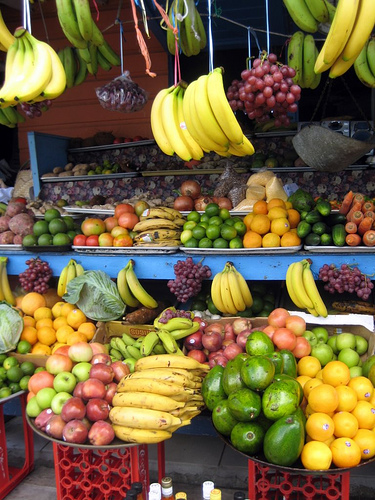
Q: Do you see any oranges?
A: Yes, there are oranges.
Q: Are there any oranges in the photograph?
A: Yes, there are oranges.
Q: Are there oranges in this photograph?
A: Yes, there are oranges.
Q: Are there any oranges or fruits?
A: Yes, there are oranges.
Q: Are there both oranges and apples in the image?
A: Yes, there are both oranges and an apple.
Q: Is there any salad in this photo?
A: No, there is no salad.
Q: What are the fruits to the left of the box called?
A: The fruits are oranges.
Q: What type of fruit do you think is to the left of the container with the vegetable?
A: The fruits are oranges.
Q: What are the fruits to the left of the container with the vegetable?
A: The fruits are oranges.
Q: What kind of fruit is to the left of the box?
A: The fruits are oranges.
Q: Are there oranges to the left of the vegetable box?
A: Yes, there are oranges to the left of the box.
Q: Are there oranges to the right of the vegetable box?
A: No, the oranges are to the left of the box.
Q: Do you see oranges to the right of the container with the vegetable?
A: No, the oranges are to the left of the box.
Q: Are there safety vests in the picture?
A: No, there are no safety vests.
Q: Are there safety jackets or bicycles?
A: No, there are no safety jackets or bicycles.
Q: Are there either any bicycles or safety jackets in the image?
A: No, there are no safety jackets or bicycles.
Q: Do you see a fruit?
A: Yes, there is a fruit.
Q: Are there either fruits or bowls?
A: Yes, there is a fruit.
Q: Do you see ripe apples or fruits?
A: Yes, there is a ripe fruit.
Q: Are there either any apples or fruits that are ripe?
A: Yes, the fruit is ripe.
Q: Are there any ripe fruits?
A: Yes, there is a ripe fruit.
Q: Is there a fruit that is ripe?
A: Yes, there is a fruit that is ripe.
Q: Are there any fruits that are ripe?
A: Yes, there is a fruit that is ripe.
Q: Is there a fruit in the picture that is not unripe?
A: Yes, there is an ripe fruit.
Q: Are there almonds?
A: No, there are no almonds.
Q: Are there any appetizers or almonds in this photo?
A: No, there are no almonds or appetizers.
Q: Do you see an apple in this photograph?
A: Yes, there are apples.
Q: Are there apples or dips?
A: Yes, there are apples.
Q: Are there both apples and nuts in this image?
A: No, there are apples but no nuts.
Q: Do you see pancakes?
A: No, there are no pancakes.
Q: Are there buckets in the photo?
A: No, there are no buckets.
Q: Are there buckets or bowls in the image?
A: No, there are no buckets or bowls.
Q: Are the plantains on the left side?
A: Yes, the plantains are on the left of the image.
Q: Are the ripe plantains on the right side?
A: No, the plantains are on the left of the image.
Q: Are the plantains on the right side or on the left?
A: The plantains are on the left of the image.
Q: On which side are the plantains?
A: The plantains are on the left of the image.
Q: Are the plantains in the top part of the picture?
A: Yes, the plantains are in the top of the image.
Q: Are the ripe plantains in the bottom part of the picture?
A: No, the plantains are in the top of the image.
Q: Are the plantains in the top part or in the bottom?
A: The plantains are in the top of the image.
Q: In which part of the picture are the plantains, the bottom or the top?
A: The plantains are in the top of the image.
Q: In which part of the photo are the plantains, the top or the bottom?
A: The plantains are in the top of the image.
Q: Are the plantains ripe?
A: Yes, the plantains are ripe.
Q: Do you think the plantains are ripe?
A: Yes, the plantains are ripe.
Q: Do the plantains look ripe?
A: Yes, the plantains are ripe.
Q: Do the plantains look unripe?
A: No, the plantains are ripe.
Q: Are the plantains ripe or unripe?
A: The plantains are ripe.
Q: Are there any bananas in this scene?
A: Yes, there are bananas.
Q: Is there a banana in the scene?
A: Yes, there are bananas.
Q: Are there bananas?
A: Yes, there are bananas.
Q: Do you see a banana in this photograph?
A: Yes, there are bananas.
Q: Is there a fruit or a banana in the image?
A: Yes, there are bananas.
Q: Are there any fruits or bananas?
A: Yes, there are bananas.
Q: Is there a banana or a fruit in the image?
A: Yes, there are bananas.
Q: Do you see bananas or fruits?
A: Yes, there are bananas.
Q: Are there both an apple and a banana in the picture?
A: Yes, there are both a banana and an apple.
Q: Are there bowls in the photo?
A: No, there are no bowls.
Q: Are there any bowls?
A: No, there are no bowls.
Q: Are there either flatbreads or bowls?
A: No, there are no bowls or flatbreads.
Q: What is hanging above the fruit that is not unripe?
A: The bananas are hanging above the fruit.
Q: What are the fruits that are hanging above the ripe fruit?
A: The fruits are bananas.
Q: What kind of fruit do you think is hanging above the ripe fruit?
A: The fruits are bananas.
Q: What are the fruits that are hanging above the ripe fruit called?
A: The fruits are bananas.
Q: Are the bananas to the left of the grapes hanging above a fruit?
A: Yes, the bananas are hanging above a fruit.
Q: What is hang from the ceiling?
A: The bananas are hang from the ceiling.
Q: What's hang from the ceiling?
A: The bananas are hang from the ceiling.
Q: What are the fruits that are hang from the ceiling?
A: The fruits are bananas.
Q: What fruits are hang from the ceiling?
A: The fruits are bananas.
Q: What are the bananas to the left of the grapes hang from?
A: The bananas are hang from the ceiling.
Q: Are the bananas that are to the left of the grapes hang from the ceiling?
A: Yes, the bananas are hang from the ceiling.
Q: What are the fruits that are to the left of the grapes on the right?
A: The fruits are bananas.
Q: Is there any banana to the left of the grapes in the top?
A: Yes, there are bananas to the left of the grapes.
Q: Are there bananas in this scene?
A: Yes, there are bananas.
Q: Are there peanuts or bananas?
A: Yes, there are bananas.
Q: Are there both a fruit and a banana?
A: Yes, there are both a banana and a fruit.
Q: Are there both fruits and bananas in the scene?
A: Yes, there are both bananas and a fruit.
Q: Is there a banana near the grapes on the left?
A: Yes, there are bananas near the grapes.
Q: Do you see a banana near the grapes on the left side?
A: Yes, there are bananas near the grapes.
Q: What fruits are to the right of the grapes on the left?
A: The fruits are bananas.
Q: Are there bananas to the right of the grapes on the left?
A: Yes, there are bananas to the right of the grapes.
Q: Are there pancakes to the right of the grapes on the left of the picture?
A: No, there are bananas to the right of the grapes.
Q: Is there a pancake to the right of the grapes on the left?
A: No, there are bananas to the right of the grapes.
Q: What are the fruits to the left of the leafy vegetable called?
A: The fruits are bananas.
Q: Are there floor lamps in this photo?
A: No, there are no floor lamps.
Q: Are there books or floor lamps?
A: No, there are no floor lamps or books.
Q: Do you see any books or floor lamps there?
A: No, there are no floor lamps or books.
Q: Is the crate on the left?
A: Yes, the crate is on the left of the image.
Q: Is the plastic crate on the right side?
A: No, the crate is on the left of the image.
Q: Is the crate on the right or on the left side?
A: The crate is on the left of the image.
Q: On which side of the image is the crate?
A: The crate is on the left of the image.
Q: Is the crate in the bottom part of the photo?
A: Yes, the crate is in the bottom of the image.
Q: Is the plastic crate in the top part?
A: No, the crate is in the bottom of the image.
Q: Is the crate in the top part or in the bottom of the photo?
A: The crate is in the bottom of the image.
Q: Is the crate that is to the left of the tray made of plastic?
A: Yes, the crate is made of plastic.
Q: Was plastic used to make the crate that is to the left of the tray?
A: Yes, the crate is made of plastic.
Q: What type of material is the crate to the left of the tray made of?
A: The crate is made of plastic.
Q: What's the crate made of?
A: The crate is made of plastic.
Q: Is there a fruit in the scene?
A: Yes, there is a fruit.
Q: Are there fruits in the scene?
A: Yes, there is a fruit.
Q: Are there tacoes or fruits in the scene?
A: Yes, there is a fruit.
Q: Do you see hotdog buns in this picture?
A: No, there are no hotdog buns.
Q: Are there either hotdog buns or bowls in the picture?
A: No, there are no hotdog buns or bowls.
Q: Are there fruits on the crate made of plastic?
A: Yes, there is a fruit on the crate.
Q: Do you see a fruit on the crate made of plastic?
A: Yes, there is a fruit on the crate.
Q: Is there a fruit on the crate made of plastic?
A: Yes, there is a fruit on the crate.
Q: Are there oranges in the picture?
A: Yes, there are oranges.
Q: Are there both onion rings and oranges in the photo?
A: No, there are oranges but no onion rings.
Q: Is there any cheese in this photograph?
A: No, there is no cheese.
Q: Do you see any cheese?
A: No, there is no cheese.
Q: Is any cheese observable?
A: No, there is no cheese.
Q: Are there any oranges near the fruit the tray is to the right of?
A: Yes, there are oranges near the fruit.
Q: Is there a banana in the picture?
A: Yes, there are bananas.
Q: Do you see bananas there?
A: Yes, there are bananas.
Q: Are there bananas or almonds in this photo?
A: Yes, there are bananas.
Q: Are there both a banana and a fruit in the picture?
A: Yes, there are both a banana and a fruit.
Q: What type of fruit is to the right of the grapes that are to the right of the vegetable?
A: The fruits are bananas.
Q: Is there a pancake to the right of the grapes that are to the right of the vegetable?
A: No, there are bananas to the right of the grapes.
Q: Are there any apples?
A: Yes, there are apples.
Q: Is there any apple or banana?
A: Yes, there are apples.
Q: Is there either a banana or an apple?
A: Yes, there are apples.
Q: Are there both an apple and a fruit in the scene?
A: Yes, there are both an apple and a fruit.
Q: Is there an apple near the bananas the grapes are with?
A: Yes, there are apples near the bananas.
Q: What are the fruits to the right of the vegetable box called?
A: The fruits are apples.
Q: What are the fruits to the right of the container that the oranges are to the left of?
A: The fruits are apples.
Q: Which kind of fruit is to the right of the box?
A: The fruits are apples.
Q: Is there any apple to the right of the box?
A: Yes, there are apples to the right of the box.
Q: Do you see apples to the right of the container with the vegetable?
A: Yes, there are apples to the right of the box.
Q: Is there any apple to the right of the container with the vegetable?
A: Yes, there are apples to the right of the box.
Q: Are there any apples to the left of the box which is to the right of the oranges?
A: No, the apples are to the right of the box.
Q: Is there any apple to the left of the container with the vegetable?
A: No, the apples are to the right of the box.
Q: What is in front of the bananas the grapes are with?
A: The apples are in front of the bananas.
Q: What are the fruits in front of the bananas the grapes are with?
A: The fruits are apples.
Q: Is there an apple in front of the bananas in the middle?
A: Yes, there are apples in front of the bananas.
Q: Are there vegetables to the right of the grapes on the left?
A: Yes, there is a vegetable to the right of the grapes.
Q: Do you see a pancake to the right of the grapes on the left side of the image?
A: No, there is a vegetable to the right of the grapes.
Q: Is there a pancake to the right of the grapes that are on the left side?
A: No, there is a vegetable to the right of the grapes.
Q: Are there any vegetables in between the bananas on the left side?
A: Yes, there is a vegetable in between the bananas.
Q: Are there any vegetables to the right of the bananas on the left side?
A: Yes, there is a vegetable to the right of the bananas.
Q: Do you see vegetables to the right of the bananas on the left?
A: Yes, there is a vegetable to the right of the bananas.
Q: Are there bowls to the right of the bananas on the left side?
A: No, there is a vegetable to the right of the bananas.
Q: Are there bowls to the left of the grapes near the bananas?
A: No, there is a vegetable to the left of the grapes.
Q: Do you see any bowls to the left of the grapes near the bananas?
A: No, there is a vegetable to the left of the grapes.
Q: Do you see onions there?
A: Yes, there are onions.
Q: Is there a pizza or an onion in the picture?
A: Yes, there are onions.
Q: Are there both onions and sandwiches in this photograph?
A: No, there are onions but no sandwiches.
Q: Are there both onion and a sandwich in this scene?
A: No, there are onions but no sandwiches.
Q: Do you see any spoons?
A: No, there are no spoons.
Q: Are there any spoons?
A: No, there are no spoons.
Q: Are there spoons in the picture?
A: No, there are no spoons.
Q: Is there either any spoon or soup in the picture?
A: No, there are no spoons or soup.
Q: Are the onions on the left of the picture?
A: Yes, the onions are on the left of the image.